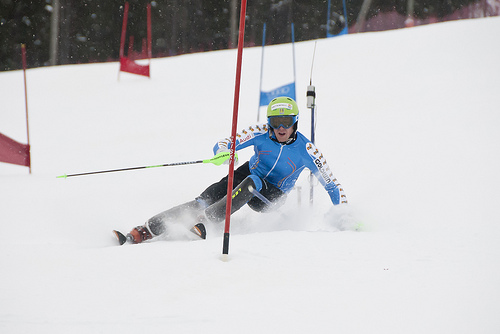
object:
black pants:
[147, 161, 284, 236]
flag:
[0, 43, 30, 173]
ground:
[0, 16, 500, 334]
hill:
[341, 0, 500, 36]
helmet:
[266, 96, 299, 118]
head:
[266, 96, 299, 142]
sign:
[0, 135, 45, 174]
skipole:
[55, 152, 237, 180]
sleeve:
[304, 144, 349, 206]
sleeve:
[215, 126, 253, 156]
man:
[168, 114, 351, 209]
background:
[0, 0, 500, 73]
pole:
[221, 0, 247, 254]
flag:
[258, 22, 298, 106]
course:
[19, 46, 236, 251]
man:
[126, 96, 347, 243]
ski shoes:
[113, 224, 154, 248]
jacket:
[212, 124, 347, 200]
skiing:
[104, 212, 224, 245]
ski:
[190, 223, 209, 240]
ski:
[111, 230, 134, 245]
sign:
[119, 57, 153, 76]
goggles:
[268, 114, 298, 130]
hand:
[331, 204, 361, 232]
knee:
[194, 195, 212, 208]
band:
[242, 174, 265, 191]